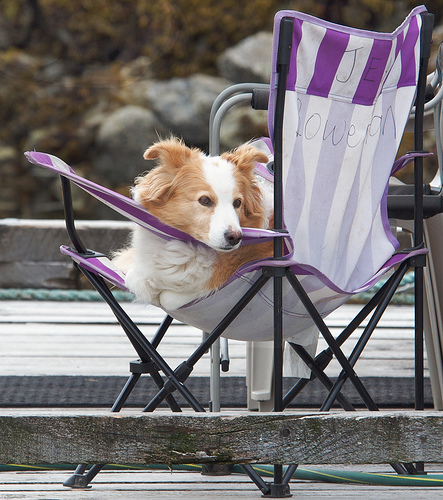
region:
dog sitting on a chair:
[115, 133, 295, 333]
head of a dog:
[144, 128, 276, 259]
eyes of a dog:
[196, 180, 245, 216]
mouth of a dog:
[194, 209, 245, 255]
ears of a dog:
[145, 129, 275, 178]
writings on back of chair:
[288, 30, 407, 157]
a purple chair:
[19, 4, 435, 498]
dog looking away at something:
[96, 124, 330, 328]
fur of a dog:
[143, 238, 208, 276]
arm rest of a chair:
[22, 140, 282, 270]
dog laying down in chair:
[125, 142, 268, 303]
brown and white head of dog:
[141, 142, 263, 249]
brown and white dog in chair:
[116, 137, 268, 298]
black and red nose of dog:
[220, 219, 244, 246]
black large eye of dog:
[197, 193, 212, 207]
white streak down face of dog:
[198, 155, 244, 245]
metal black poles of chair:
[91, 314, 239, 422]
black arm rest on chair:
[249, 83, 285, 110]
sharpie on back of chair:
[336, 48, 397, 96]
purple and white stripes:
[279, 37, 408, 103]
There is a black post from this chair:
[268, 310, 311, 425]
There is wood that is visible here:
[330, 408, 351, 452]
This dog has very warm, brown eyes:
[197, 191, 227, 208]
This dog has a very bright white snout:
[212, 206, 266, 290]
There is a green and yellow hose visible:
[350, 462, 368, 497]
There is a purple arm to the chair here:
[118, 196, 131, 225]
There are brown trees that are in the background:
[101, 28, 122, 65]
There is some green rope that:
[38, 276, 58, 310]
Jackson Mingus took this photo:
[118, 44, 332, 422]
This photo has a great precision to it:
[125, 98, 337, 476]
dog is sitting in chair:
[100, 128, 298, 317]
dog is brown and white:
[106, 124, 297, 315]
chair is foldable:
[14, 5, 430, 498]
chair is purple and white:
[20, 7, 442, 498]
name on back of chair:
[281, 36, 401, 151]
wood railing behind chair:
[1, 403, 442, 473]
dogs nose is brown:
[221, 228, 244, 248]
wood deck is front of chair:
[0, 280, 437, 406]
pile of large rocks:
[85, 22, 309, 175]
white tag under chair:
[278, 320, 323, 387]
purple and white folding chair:
[27, 6, 432, 497]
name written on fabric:
[291, 45, 399, 141]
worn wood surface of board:
[2, 415, 439, 461]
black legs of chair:
[65, 262, 423, 495]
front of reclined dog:
[127, 138, 268, 305]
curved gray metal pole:
[207, 90, 251, 148]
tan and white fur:
[138, 142, 264, 251]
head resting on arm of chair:
[33, 149, 282, 252]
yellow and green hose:
[0, 464, 442, 486]